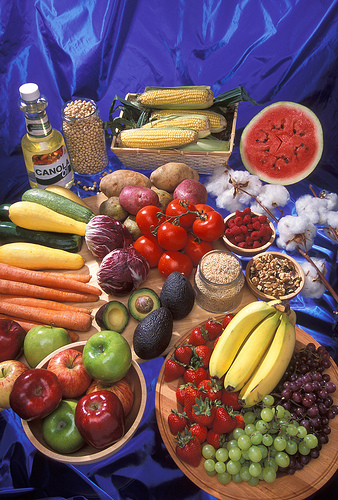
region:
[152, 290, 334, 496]
Fruit on top of a round wooden tray.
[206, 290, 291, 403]
Yellow bananas on top of the wooden tray.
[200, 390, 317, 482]
Green grapes on the wooden tray.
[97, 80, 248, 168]
Corn on the cob in a brown basket.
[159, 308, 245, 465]
Red strawberries on top of the wooden tray.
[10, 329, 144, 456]
A brown wooden bowl filled with apples.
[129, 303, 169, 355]
A ripe avacado with a dark skin.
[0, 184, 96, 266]
Yellow and green squash.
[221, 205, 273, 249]
A bowl of red raspberries.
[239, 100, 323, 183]
Half of a watermelon with black seeds.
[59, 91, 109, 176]
The jar is full of beans.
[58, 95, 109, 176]
The jar is clear glass.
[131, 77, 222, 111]
The corn is on the cob.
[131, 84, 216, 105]
The corn is yellow.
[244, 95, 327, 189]
The watermelon has been cut.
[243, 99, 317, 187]
The watermelon is ripe.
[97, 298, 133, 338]
The avocado is cut in half.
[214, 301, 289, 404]
The bananas are yellow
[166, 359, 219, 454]
The strawberries have green stems.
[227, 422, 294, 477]
The grapes are green.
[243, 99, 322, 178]
slice of watermelon with seeds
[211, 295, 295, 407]
yellow bunch of bananas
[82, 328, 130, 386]
a green granny smith apple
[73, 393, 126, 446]
a deep red delicious apple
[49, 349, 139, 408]
the lighter red fuji has a hint of of a stripe in the skin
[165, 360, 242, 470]
red ripe strawberries with green caps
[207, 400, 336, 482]
green seedless grapes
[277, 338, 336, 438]
bunchof red grapes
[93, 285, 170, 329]
halved avacado with pit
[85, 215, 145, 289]
Radicchio has red leaves with white veins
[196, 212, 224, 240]
vegetable on the tray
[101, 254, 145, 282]
vegetable on the tray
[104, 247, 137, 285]
vegetable on the tray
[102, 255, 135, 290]
vegetable on the tray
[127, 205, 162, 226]
vegetable on the tray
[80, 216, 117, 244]
vegetable on the tray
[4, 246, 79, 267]
vegetable on the tray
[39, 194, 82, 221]
vegetable on the tray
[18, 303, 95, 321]
vegetable on the tray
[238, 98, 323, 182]
watermelon cut in half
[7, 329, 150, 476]
apples in a bowl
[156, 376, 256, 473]
a pile of red strawberries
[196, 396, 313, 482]
a pile of green grapes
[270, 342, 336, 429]
a pile of purple grapes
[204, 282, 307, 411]
a bunch of yellow bananas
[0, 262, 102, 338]
long, orange carrots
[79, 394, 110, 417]
light shining on the top of the apple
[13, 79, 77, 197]
canola oil in a bottle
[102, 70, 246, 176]
corn in a basket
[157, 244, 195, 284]
A piece of food.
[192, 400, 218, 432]
A piece of food.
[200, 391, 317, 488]
bunch of green grapes on platter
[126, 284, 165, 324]
half an avocado with seed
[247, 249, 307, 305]
wooden bowl with walnut parts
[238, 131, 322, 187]
cut open half of watermelon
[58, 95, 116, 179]
large jar filled with dried beans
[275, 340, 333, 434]
bunch of purple grapes on platter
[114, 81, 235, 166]
six ears of corn in wicker basket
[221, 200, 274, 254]
wooden bowl of red raspberries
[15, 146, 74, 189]
bottle of canola vegetable oil